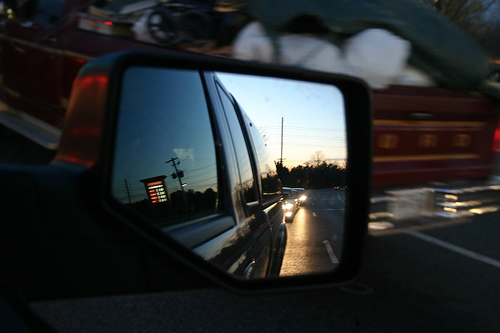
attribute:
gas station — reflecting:
[139, 175, 173, 219]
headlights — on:
[286, 202, 294, 218]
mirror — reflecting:
[113, 68, 344, 282]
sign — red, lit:
[146, 182, 166, 203]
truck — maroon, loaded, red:
[2, 4, 498, 233]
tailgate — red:
[370, 83, 496, 185]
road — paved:
[280, 189, 347, 277]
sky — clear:
[216, 74, 347, 171]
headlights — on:
[299, 194, 307, 203]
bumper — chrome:
[368, 176, 498, 236]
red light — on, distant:
[334, 187, 338, 190]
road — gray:
[30, 214, 495, 333]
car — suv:
[113, 64, 287, 280]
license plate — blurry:
[389, 190, 434, 220]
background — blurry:
[2, 1, 500, 332]